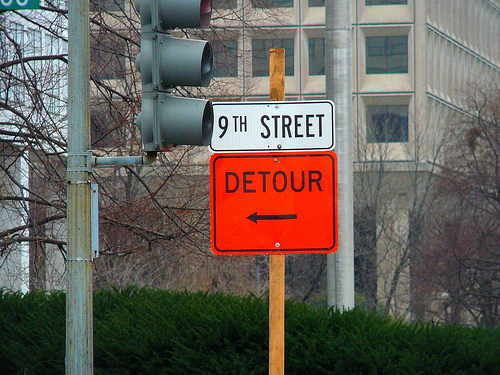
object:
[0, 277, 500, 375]
bushes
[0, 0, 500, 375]
city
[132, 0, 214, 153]
light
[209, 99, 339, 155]
sign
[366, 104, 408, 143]
window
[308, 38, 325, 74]
window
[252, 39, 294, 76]
window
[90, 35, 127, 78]
window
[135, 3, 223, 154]
traffic light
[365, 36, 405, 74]
reflection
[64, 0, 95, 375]
steel poll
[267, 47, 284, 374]
pole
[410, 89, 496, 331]
trees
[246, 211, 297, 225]
arrow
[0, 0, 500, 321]
building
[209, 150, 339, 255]
detour sign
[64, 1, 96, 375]
pole